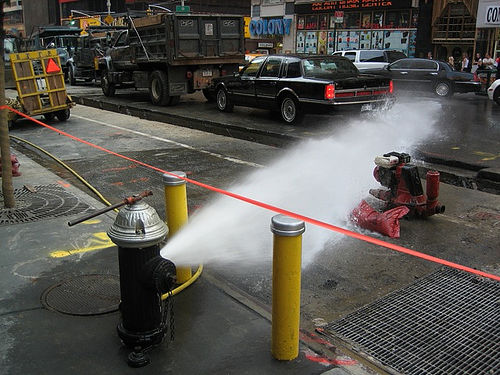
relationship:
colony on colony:
[248, 18, 291, 35] [249, 18, 291, 35]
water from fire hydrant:
[156, 97, 444, 277] [68, 190, 177, 365]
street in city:
[9, 80, 499, 372] [4, 1, 499, 368]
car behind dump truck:
[201, 53, 393, 126] [89, 3, 249, 106]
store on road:
[287, 9, 494, 83] [216, 50, 456, 297]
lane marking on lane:
[71, 108, 266, 168] [82, 96, 331, 345]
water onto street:
[159, 87, 448, 267] [16, 60, 498, 365]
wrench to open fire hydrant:
[68, 188, 152, 227] [68, 190, 177, 365]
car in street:
[201, 53, 393, 126] [12, 45, 498, 207]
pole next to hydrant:
[269, 214, 305, 361] [101, 174, 223, 334]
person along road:
[447, 52, 455, 71] [378, 91, 490, 141]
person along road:
[457, 50, 469, 72] [378, 91, 490, 141]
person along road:
[473, 48, 480, 65] [378, 91, 490, 141]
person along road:
[479, 46, 493, 66] [378, 91, 490, 141]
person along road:
[448, 55, 455, 69] [378, 91, 490, 141]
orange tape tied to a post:
[157, 152, 428, 291] [247, 194, 345, 359]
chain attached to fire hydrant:
[156, 284, 182, 313] [84, 170, 222, 363]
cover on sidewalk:
[41, 273, 121, 314] [7, 162, 270, 371]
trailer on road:
[6, 45, 74, 123] [14, 110, 127, 200]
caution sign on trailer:
[46, 58, 61, 72] [0, 44, 73, 129]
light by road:
[67, 12, 78, 26] [9, 81, 498, 375]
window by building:
[285, 16, 451, 84] [282, 7, 423, 73]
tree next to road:
[2, 1, 24, 213] [9, 58, 496, 366]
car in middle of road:
[196, 46, 400, 128] [156, 23, 382, 343]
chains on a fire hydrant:
[154, 263, 177, 342] [98, 168, 216, 357]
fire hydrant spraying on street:
[68, 190, 177, 365] [183, 73, 470, 280]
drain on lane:
[323, 261, 498, 374] [82, 96, 331, 345]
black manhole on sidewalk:
[45, 273, 125, 316] [1, 141, 374, 373]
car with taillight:
[196, 46, 400, 128] [322, 81, 337, 103]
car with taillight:
[196, 46, 400, 128] [385, 75, 394, 95]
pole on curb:
[267, 210, 306, 360] [0, 147, 370, 374]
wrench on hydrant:
[63, 184, 164, 249] [101, 194, 203, 309]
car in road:
[201, 53, 393, 126] [9, 81, 498, 375]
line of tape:
[264, 207, 374, 256] [6, 101, 498, 281]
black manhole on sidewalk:
[45, 273, 125, 316] [1, 239, 103, 356]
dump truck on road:
[89, 3, 248, 113] [51, 53, 498, 190]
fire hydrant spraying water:
[68, 190, 177, 365] [277, 167, 333, 265]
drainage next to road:
[16, 175, 89, 228] [9, 58, 496, 366]